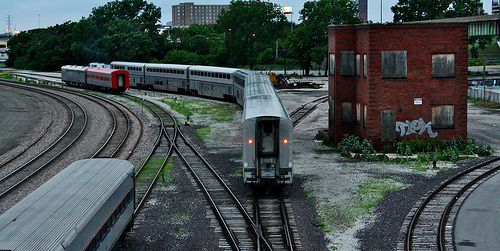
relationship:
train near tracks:
[97, 56, 300, 193] [3, 80, 491, 247]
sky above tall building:
[0, 0, 499, 37] [168, 3, 226, 26]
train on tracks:
[97, 56, 300, 193] [3, 80, 491, 247]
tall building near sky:
[168, 3, 226, 26] [0, 0, 499, 37]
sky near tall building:
[0, 0, 499, 37] [168, 3, 226, 26]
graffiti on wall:
[392, 114, 435, 140] [365, 23, 467, 147]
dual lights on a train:
[245, 137, 295, 146] [236, 73, 299, 185]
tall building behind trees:
[168, 3, 226, 26] [10, 5, 452, 75]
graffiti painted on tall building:
[392, 114, 435, 140] [168, 3, 226, 26]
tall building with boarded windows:
[168, 3, 226, 26] [330, 54, 453, 127]